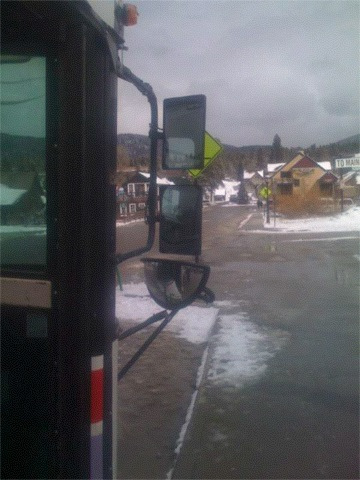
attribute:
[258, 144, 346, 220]
house — brown, two story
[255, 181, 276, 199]
traffic signal — yellow, four sided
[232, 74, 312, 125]
cloud — white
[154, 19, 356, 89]
sky — blue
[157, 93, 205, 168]
mirror — gray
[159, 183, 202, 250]
mirror — gray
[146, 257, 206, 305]
mirror — gray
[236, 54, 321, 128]
clouds — white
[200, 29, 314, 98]
sky — blue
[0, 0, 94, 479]
door — open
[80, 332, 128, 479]
design — red, white, blue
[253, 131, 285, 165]
trees — large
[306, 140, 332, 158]
trees — large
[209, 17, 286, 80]
clods — white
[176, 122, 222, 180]
sign — yellow, warning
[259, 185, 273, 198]
sign — yellow, warning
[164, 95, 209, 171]
mirror — one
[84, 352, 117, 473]
stripe — red, purple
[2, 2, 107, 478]
bus door — open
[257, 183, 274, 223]
caution sign — yellow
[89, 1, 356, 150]
sky — grey, cloudy, blue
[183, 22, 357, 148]
clouds — white